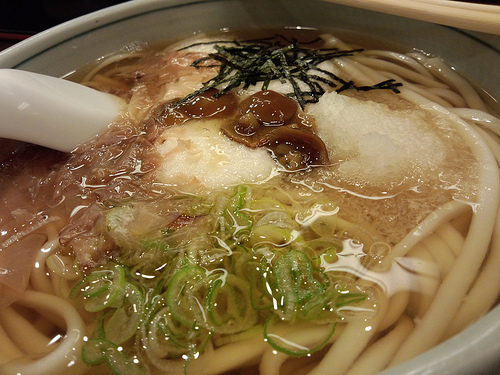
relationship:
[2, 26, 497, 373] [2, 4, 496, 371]
food in bowl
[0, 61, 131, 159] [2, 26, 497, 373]
spoon in food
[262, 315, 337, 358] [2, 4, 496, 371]
onion lying in bowl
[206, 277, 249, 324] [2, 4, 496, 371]
onion lying in bowl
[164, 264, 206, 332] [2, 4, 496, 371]
onion lying in bowl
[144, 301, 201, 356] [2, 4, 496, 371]
onion lying in bowl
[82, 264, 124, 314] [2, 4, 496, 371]
onion lying in bowl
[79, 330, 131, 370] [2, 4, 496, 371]
onion lying in bowl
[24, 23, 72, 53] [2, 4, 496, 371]
edge belonging to bowl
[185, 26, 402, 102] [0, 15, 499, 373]
spices in soup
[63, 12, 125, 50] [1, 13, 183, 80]
trim on bowl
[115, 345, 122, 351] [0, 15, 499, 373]
spots on soup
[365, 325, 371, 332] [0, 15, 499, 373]
spots on soup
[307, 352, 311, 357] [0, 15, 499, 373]
spots on soup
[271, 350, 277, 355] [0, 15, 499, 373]
spots on soup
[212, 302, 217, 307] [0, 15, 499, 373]
spots on soup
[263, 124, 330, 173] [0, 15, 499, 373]
mushroom in soup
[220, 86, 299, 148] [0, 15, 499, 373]
mushroom in soup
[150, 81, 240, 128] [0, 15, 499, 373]
mushroom in soup